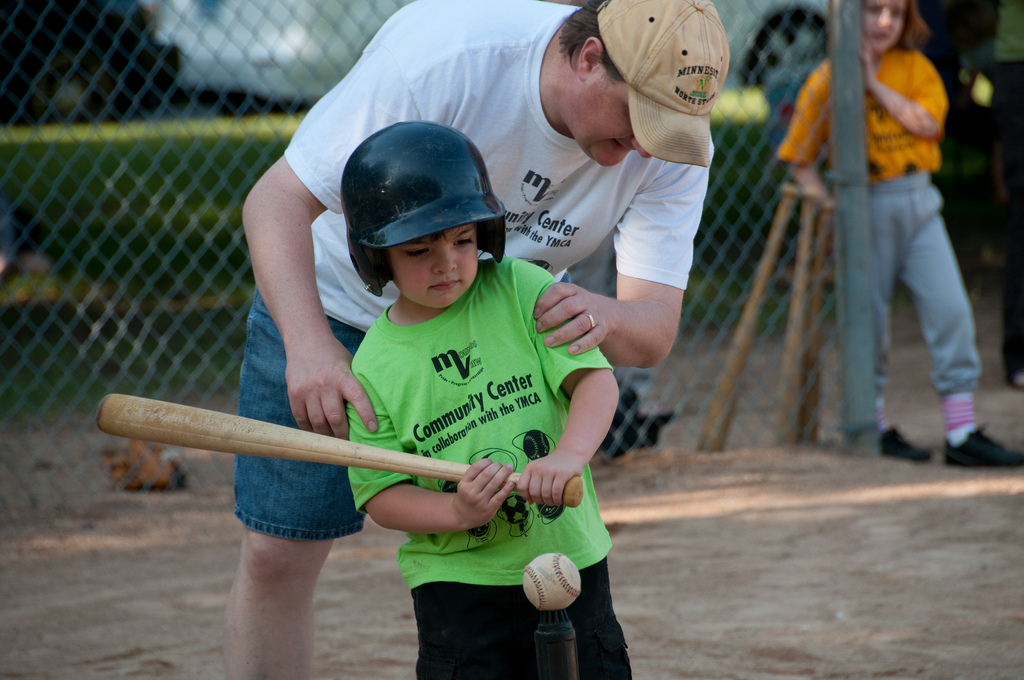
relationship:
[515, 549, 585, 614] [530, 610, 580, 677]
baseball sitting on top of tee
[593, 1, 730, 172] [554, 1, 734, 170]
hat worn on head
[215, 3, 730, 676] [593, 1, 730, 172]
man wearing hat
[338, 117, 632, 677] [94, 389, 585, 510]
boy holding baseball bat